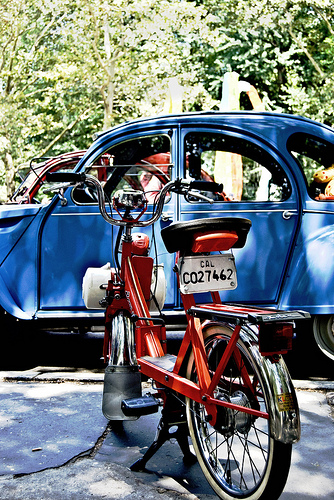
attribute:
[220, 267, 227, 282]
number — black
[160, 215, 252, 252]
seat — black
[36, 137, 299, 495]
bike — red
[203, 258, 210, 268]
letter — black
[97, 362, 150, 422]
flap — black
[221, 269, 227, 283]
number — black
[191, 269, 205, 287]
number — black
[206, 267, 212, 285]
number — black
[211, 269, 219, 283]
number — black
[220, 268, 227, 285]
number — black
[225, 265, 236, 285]
number — black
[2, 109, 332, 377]
car — parked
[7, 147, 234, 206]
car — parked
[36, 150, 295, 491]
scooter — red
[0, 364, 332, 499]
ground — gray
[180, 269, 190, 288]
letter — black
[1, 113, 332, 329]
car — blue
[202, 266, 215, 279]
number — black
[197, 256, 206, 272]
letter — black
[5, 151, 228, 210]
car — red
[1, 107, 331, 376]
bug — blue